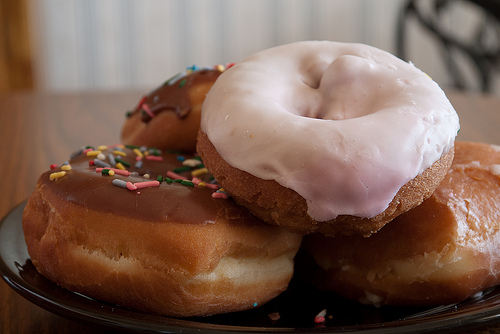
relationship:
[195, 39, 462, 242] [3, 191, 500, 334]
donut on plate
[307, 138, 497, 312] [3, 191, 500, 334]
donut on plate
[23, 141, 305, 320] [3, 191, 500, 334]
donut on plate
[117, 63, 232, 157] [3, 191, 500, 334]
donut on plate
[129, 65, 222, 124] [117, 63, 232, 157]
chocolate on donut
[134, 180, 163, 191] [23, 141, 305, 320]
sprinkle on donut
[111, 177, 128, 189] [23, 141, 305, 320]
sprinkle on donut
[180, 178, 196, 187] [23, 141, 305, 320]
sprinkle on donut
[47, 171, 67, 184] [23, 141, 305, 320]
sprinkle on donut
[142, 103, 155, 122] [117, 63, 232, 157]
sprinkle on donut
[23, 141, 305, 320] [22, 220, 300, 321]
donut has bottom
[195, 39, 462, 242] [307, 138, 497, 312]
donut next to donut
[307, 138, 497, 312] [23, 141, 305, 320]
donut next to donut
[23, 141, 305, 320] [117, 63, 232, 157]
donut next to donut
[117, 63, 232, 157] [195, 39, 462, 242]
donut next to donut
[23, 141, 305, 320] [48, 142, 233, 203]
donut has sprinkles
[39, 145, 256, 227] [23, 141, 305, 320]
frosting on donut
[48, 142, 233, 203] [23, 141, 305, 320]
sprinkles are on donut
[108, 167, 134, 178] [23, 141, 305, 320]
sprinkle on donut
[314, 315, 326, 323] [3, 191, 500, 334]
sprinkle on plate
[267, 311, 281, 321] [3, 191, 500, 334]
sprinkle on plate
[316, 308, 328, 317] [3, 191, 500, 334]
sprinkle on plate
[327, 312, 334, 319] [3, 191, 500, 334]
sprinkle on plate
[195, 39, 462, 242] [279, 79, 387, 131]
donut has hole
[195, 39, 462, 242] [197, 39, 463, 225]
donut has frosting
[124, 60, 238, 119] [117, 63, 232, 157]
sprinkles are on donut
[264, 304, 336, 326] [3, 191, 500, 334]
crumbs are on plate